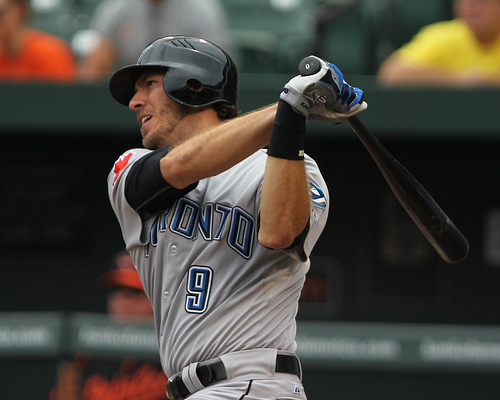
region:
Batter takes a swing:
[40, 15, 477, 366]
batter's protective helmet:
[100, 25, 240, 130]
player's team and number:
[130, 185, 250, 320]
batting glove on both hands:
[280, 45, 370, 125]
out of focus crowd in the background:
[0, 0, 495, 50]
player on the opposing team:
[65, 245, 165, 390]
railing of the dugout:
[320, 310, 495, 370]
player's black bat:
[365, 115, 465, 265]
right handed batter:
[98, 31, 470, 303]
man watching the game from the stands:
[365, 1, 496, 93]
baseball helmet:
[100, 21, 238, 121]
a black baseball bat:
[294, 59, 476, 271]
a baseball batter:
[90, 19, 472, 398]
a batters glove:
[252, 48, 370, 168]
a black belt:
[147, 342, 312, 395]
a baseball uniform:
[97, 137, 335, 373]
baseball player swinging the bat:
[89, 18, 470, 396]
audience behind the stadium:
[358, 2, 498, 97]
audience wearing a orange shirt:
[0, 4, 99, 90]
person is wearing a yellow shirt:
[369, 0, 498, 89]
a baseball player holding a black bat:
[89, 32, 466, 398]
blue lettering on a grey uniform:
[141, 199, 258, 260]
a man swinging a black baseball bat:
[89, 33, 459, 393]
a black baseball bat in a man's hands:
[285, 55, 464, 265]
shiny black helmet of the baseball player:
[116, 34, 246, 120]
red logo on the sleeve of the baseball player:
[104, 152, 139, 180]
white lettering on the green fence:
[341, 327, 492, 373]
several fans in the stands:
[1, 0, 479, 82]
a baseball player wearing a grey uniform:
[68, 42, 325, 399]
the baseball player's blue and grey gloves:
[272, 57, 369, 137]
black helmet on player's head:
[118, 28, 245, 115]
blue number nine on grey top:
[181, 244, 223, 331]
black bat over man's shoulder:
[353, 91, 481, 279]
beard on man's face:
[124, 114, 199, 142]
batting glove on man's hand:
[277, 64, 345, 132]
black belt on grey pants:
[151, 355, 323, 398]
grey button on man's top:
[166, 229, 183, 261]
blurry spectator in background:
[68, 259, 148, 321]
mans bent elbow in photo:
[251, 201, 324, 275]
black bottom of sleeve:
[126, 157, 186, 212]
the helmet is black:
[94, 5, 281, 144]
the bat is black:
[277, 31, 484, 321]